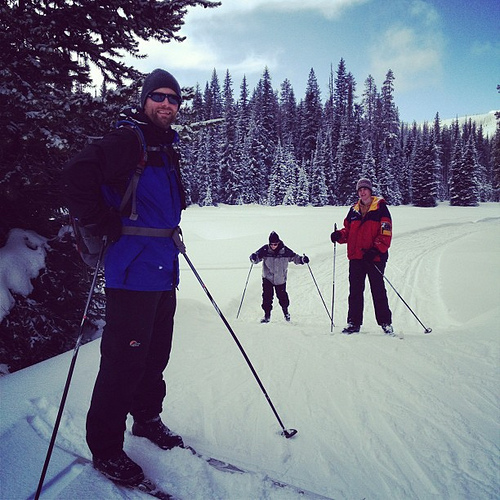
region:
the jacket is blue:
[94, 134, 201, 294]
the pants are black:
[103, 291, 183, 444]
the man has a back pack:
[69, 64, 206, 484]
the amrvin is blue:
[134, 69, 188, 102]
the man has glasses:
[66, 75, 285, 488]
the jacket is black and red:
[337, 204, 392, 262]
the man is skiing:
[251, 229, 293, 324]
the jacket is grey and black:
[246, 246, 301, 288]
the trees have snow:
[253, 107, 380, 167]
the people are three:
[71, 79, 416, 489]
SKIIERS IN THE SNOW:
[71, 20, 441, 464]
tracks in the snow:
[380, 393, 474, 484]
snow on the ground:
[303, 354, 373, 387]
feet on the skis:
[80, 413, 206, 493]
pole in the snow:
[266, 412, 301, 452]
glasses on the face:
[144, 87, 187, 103]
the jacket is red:
[345, 222, 370, 234]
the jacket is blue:
[135, 263, 165, 290]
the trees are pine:
[381, 133, 472, 183]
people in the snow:
[75, 55, 445, 392]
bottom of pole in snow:
[268, 419, 311, 445]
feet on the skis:
[96, 420, 228, 495]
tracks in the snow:
[319, 382, 486, 487]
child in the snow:
[237, 203, 327, 322]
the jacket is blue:
[133, 182, 178, 219]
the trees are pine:
[311, 128, 451, 178]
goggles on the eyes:
[140, 91, 179, 107]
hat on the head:
[140, 61, 176, 96]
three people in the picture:
[153, 83, 383, 426]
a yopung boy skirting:
[244, 223, 324, 318]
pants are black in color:
[101, 287, 166, 389]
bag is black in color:
[56, 152, 115, 244]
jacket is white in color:
[258, 242, 303, 289]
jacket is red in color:
[343, 208, 395, 248]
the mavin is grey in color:
[339, 169, 388, 196]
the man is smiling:
[89, 62, 206, 291]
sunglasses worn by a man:
[143, 87, 180, 108]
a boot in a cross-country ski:
[82, 438, 147, 490]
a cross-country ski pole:
[167, 222, 309, 444]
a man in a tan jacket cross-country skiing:
[230, 224, 337, 334]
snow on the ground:
[332, 354, 468, 455]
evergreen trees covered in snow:
[214, 95, 366, 200]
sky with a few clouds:
[204, 19, 456, 76]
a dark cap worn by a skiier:
[137, 68, 187, 108]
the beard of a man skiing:
[147, 104, 178, 129]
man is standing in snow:
[111, 407, 296, 436]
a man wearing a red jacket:
[326, 174, 403, 343]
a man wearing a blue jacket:
[80, 63, 205, 488]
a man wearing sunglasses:
[68, 60, 194, 492]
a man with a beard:
[77, 60, 202, 491]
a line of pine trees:
[15, 52, 490, 207]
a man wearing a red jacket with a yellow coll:
[318, 173, 403, 341]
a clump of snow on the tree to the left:
[0, 225, 50, 330]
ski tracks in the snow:
[390, 236, 472, 342]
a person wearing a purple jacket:
[245, 228, 311, 325]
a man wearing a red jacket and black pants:
[325, 169, 402, 343]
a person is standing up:
[55, 53, 221, 478]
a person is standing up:
[244, 224, 312, 320]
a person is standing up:
[327, 169, 399, 334]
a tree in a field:
[447, 133, 479, 206]